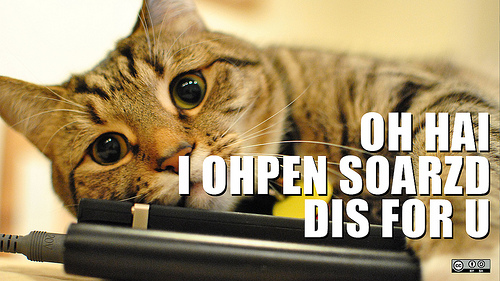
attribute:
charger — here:
[0, 232, 67, 263]